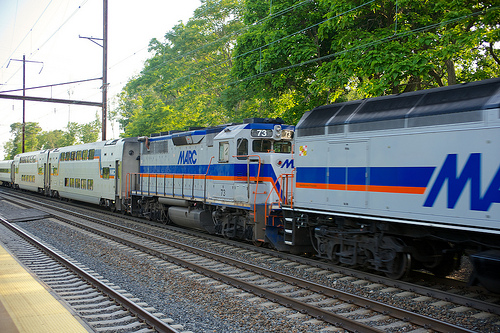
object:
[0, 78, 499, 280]
train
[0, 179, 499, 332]
track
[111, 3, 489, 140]
trees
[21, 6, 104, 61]
power lines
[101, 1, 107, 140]
pole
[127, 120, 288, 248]
engine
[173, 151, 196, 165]
words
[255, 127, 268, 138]
number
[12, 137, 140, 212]
cars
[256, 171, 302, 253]
steps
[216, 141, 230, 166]
window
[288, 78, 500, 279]
train car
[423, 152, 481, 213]
letter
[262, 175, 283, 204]
handle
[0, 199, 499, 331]
gravel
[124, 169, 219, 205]
walkway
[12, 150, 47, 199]
car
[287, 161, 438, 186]
line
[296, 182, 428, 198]
line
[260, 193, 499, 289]
bottom